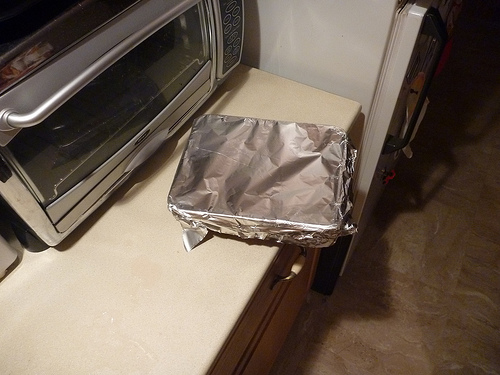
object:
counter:
[4, 63, 361, 375]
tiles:
[384, 244, 497, 372]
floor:
[267, 2, 500, 375]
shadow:
[266, 240, 395, 375]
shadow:
[379, 57, 499, 234]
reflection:
[39, 62, 167, 169]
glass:
[7, 2, 212, 207]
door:
[0, 2, 219, 247]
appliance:
[0, 0, 246, 248]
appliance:
[239, 1, 445, 296]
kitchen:
[0, 0, 499, 375]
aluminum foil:
[164, 111, 359, 253]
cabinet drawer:
[206, 240, 315, 374]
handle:
[381, 37, 441, 155]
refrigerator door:
[311, 0, 455, 297]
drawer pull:
[268, 246, 309, 290]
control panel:
[215, 1, 245, 78]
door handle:
[0, 1, 199, 133]